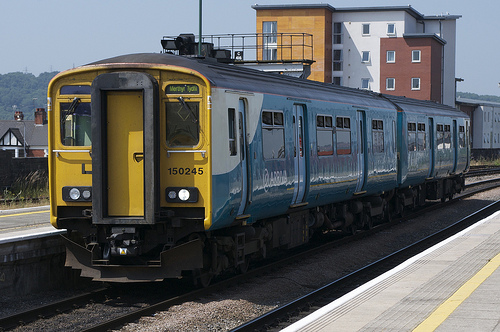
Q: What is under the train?
A: Tracks.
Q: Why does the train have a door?
A: To let the passengers enter.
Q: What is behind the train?
A: Building.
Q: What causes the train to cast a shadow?
A: The sun.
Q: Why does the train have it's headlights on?
A: Safety.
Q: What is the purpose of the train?
A: Transportation.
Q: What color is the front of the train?
A: Yellow.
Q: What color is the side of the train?
A: Blue.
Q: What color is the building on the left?
A: Orange.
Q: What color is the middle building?
A: White.